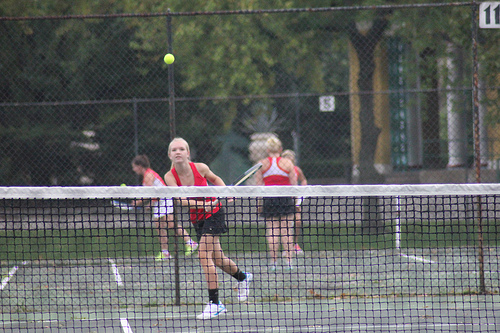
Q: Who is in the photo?
A: Women.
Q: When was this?
A: Daytime.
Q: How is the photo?
A: Blurry.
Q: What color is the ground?
A: Grey.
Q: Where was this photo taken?
A: At the tennis court.